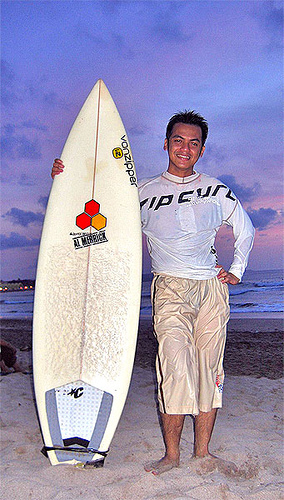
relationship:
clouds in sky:
[7, 150, 50, 248] [5, 69, 50, 219]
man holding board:
[134, 108, 256, 475] [32, 79, 143, 469]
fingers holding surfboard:
[47, 151, 69, 179] [31, 68, 140, 388]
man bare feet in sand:
[51, 107, 255, 475] [1, 308, 281, 498]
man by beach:
[51, 107, 255, 475] [110, 473, 153, 498]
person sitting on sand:
[0, 338, 29, 375] [127, 429, 149, 482]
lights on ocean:
[1, 285, 33, 291] [248, 266, 281, 307]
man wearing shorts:
[51, 107, 255, 475] [145, 272, 239, 396]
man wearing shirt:
[51, 107, 255, 475] [129, 170, 262, 284]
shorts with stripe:
[148, 266, 231, 418] [147, 273, 165, 412]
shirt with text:
[137, 166, 255, 280] [139, 185, 237, 208]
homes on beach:
[3, 275, 30, 286] [2, 317, 279, 496]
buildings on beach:
[21, 285, 30, 290] [2, 317, 279, 496]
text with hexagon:
[70, 229, 108, 249] [82, 198, 100, 216]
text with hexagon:
[70, 229, 108, 249] [90, 211, 107, 230]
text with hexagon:
[70, 229, 108, 249] [75, 211, 91, 229]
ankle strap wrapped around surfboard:
[36, 443, 111, 464] [28, 75, 233, 463]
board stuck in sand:
[32, 79, 143, 469] [51, 466, 113, 491]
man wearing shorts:
[51, 107, 255, 475] [148, 266, 231, 418]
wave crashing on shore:
[0, 271, 284, 314] [0, 310, 281, 380]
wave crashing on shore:
[228, 301, 276, 313] [0, 310, 281, 380]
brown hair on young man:
[161, 108, 209, 143] [129, 107, 256, 475]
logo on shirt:
[138, 184, 235, 210] [137, 166, 255, 280]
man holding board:
[51, 107, 255, 475] [31, 76, 140, 466]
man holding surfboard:
[51, 107, 255, 475] [31, 70, 155, 399]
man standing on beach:
[51, 107, 255, 475] [0, 318, 284, 500]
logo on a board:
[69, 198, 107, 249] [32, 79, 143, 469]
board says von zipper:
[32, 79, 143, 469] [120, 128, 139, 191]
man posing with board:
[51, 107, 255, 475] [32, 79, 143, 469]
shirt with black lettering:
[137, 169, 255, 283] [139, 183, 235, 210]